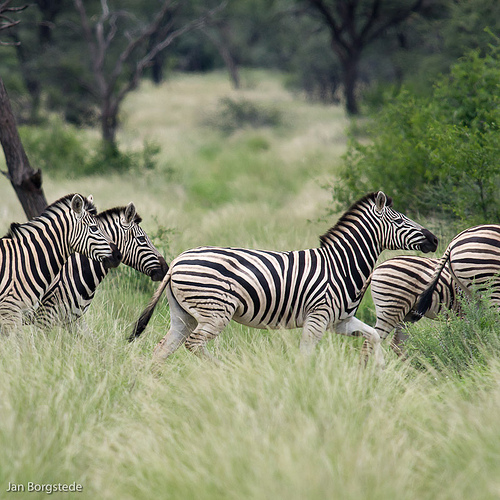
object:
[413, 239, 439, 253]
mouth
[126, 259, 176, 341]
tail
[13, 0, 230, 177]
tree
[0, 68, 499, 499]
grass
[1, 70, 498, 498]
ground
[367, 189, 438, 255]
head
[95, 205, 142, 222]
mane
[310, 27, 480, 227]
tree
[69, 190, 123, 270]
head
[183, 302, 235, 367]
leg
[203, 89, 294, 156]
bush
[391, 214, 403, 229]
eye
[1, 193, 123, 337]
zebras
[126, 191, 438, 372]
zebras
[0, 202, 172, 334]
zebras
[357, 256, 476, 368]
zebras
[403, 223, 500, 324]
zebras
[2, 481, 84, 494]
watermark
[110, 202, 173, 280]
head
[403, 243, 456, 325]
tail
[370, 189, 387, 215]
ear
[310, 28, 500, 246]
shrub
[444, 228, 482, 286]
zebra back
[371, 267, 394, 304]
zebra back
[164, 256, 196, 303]
zebra back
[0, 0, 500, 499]
background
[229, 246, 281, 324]
stripes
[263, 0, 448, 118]
tree